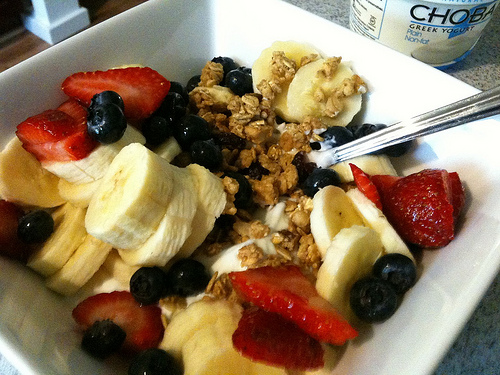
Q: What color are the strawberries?
A: Red.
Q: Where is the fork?
A: In the bowl.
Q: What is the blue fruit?
A: Blueberries.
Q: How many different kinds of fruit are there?
A: 3.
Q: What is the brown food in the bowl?
A: Granola.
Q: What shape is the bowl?
A: Square.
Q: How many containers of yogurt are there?
A: 1.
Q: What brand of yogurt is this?
A: Chobani.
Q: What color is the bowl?
A: White.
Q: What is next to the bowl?
A: Yogurt.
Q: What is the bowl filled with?
A: Fruit and granola.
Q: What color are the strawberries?
A: Red.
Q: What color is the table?
A: Grey.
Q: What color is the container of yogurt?
A: Blue and White.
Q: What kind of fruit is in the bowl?
A: Strawberries, Bananas, and blueberries.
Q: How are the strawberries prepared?
A: Sliced.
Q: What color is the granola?
A: Brown.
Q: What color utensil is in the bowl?
A: Silver.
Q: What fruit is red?
A: Strawberry.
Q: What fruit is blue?
A: Blueberries.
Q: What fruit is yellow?
A: Banana.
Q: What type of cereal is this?
A: Granola.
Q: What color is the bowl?
A: White.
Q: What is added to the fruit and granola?
A: Milk.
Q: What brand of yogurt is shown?
A: Chobani.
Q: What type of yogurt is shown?
A: Greek.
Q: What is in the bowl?
A: Yogurt.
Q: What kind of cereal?
A: Bran.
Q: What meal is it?
A: Breakfast.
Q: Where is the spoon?
A: Bowl.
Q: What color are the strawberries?
A: Red.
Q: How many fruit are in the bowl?
A: Three.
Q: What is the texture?
A: Crunchy.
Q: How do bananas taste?
A: Sweet.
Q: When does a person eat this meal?
A: At breakfast.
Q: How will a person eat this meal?
A: With the silver spoon.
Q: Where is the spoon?
A: Under the granola.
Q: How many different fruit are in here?
A: Three.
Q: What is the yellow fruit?
A: Banana.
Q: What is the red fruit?
A: Strawberries.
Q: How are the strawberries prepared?
A: Sliced.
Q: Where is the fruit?
A: In a bowl.